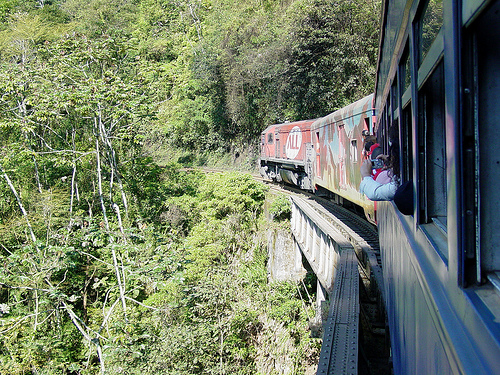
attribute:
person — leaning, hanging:
[353, 120, 406, 208]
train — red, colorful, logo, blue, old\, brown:
[260, 114, 311, 192]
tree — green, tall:
[305, 30, 349, 96]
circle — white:
[281, 126, 303, 160]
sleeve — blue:
[373, 188, 403, 201]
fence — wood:
[213, 177, 227, 195]